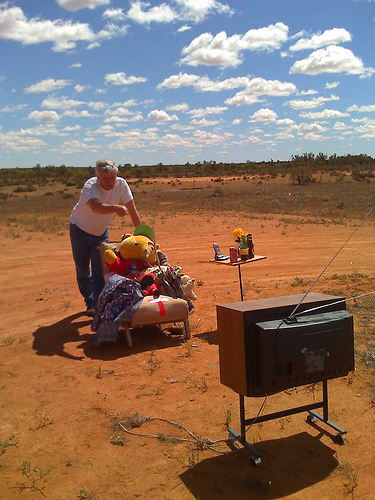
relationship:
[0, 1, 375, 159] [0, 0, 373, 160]
clouds in sky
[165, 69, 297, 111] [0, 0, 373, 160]
clouds in sky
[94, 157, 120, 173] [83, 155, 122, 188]
hair on top of head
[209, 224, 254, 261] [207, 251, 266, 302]
items on top of table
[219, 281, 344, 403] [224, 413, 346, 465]
television on top of wheels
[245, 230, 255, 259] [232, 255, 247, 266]
beer bottle on top of table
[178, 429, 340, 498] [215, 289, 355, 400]
shadow of tv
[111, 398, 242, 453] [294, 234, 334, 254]
brown rope on top of ground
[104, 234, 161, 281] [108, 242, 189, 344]
bear sitting in chair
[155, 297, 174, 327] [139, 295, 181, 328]
red tape on front of chair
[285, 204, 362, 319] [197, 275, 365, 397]
antenna on top of television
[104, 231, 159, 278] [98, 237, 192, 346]
bear on top of chair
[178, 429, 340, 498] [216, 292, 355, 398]
shadow of television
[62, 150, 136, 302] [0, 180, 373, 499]
man in desert